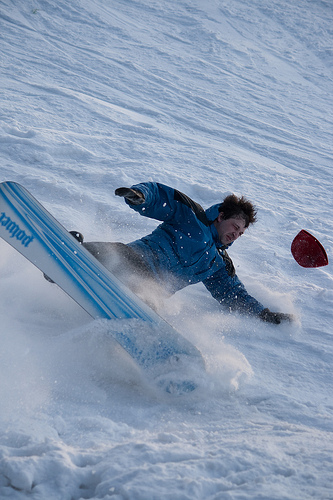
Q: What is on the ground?
A: Snow.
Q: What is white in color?
A: The snow.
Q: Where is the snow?
A: On the ground.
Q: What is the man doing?
A: Falling.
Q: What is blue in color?
A: The coat.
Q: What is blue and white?
A: Snowboard.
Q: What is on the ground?
A: Tracks.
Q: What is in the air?
A: A hat.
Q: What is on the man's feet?
A: Snowboard.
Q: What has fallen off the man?
A: Hat.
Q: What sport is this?
A: Snowboard.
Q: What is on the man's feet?
A: Snowboard.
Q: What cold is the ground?
A: White.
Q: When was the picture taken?
A: During winter.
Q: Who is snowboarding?
A: The man.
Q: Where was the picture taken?
A: Ski slope.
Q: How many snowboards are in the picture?
A: 1.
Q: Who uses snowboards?
A: People.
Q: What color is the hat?
A: Red.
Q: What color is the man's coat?
A: Blue.